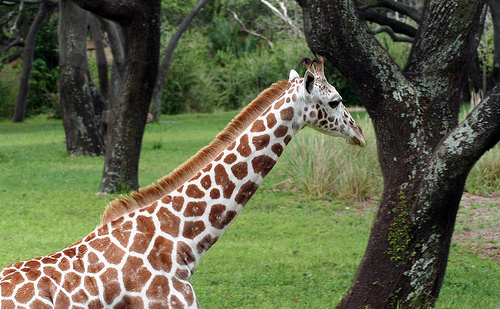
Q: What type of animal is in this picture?
A: Giraffe.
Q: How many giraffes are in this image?
A: One.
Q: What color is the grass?
A: Green.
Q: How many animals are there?
A: One.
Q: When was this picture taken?
A: Daytime.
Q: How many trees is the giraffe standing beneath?
A: One.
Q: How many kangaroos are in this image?
A: Zero.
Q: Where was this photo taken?
A: In a zoo.